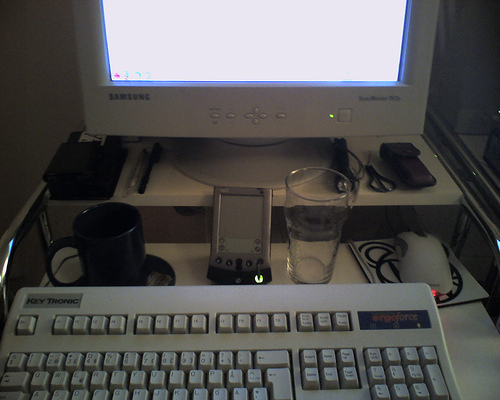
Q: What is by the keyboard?
A: Coffee mug.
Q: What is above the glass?
A: Blank monitor.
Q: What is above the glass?
A: Samsung monitor.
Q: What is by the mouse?
A: Empty glass.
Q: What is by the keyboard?
A: Black mug.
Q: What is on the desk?
A: White keyboard.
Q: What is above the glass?
A: White screen.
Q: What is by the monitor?
A: Empty cup.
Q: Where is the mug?
A: On the desk.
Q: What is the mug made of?
A: Ceramic.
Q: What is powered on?
A: The computer.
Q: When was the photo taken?
A: Night.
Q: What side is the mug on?
A: Left.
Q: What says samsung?
A: The monitor.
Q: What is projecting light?
A: The screen.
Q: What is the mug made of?
A: Ceramic.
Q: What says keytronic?
A: The keyboard.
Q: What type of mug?
A: Coffee.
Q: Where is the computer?
A: The desk.